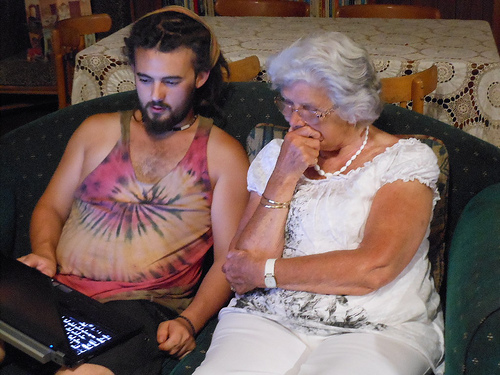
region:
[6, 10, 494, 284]
man sitting next to woman on a green couch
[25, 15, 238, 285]
man wearing a tie-dyed sleeveless shirt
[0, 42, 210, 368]
laptop computer on man's lap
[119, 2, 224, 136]
brown cloth around man's head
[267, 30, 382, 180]
woman wearing a white beaded necklace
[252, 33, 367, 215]
woman holding her hand to her mouth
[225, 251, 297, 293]
white watch on woman's wrist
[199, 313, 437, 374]
woman wearing white pants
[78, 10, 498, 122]
tablecloth with circular design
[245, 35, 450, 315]
cushion behind woman's back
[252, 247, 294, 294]
part of a watch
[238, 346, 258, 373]
part of a trouser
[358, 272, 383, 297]
part of an elbow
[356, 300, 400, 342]
edge of a top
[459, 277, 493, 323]
part of a couch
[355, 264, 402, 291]
part of an elbow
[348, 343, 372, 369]
part of a trouser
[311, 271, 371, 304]
edge of an arm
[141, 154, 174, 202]
edge of a vest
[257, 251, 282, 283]
part of a watch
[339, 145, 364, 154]
part of a necklace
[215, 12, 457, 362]
A woman with white hair wearing a white top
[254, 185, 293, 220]
Gold bracelets on a woman's arm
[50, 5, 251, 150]
A man with brown hair wearing a necklace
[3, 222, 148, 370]
A laptop computer with a lit up keyboard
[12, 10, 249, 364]
A man with dark hair wearing a tank top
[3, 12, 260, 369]
A man with a beard using a laptop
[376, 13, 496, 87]
A white tablecloth on a table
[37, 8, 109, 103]
A brown wooden chair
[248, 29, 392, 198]
An elderly woman wearing glasses and a necklace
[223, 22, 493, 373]
A woman sitting on a green couch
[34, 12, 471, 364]
man and woman siting down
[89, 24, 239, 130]
man with dredd locks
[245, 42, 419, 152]
woman with gray hair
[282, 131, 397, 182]
pearl neclace on old woman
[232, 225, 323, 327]
white watch on womans wrist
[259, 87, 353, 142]
eyeglasses on woman's face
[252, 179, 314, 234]
bracelets on wrist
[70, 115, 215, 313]
tie dye tank top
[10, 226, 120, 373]
laptop on man's lap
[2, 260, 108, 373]
laptop with lighted keyboard